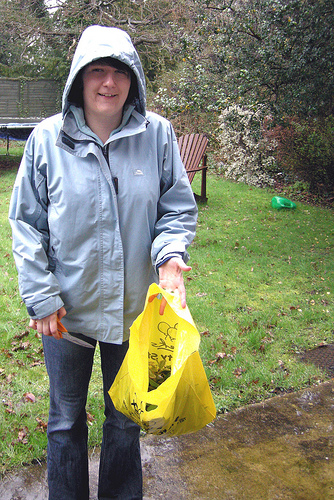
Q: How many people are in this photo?
A: One.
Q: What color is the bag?
A: Yellow.